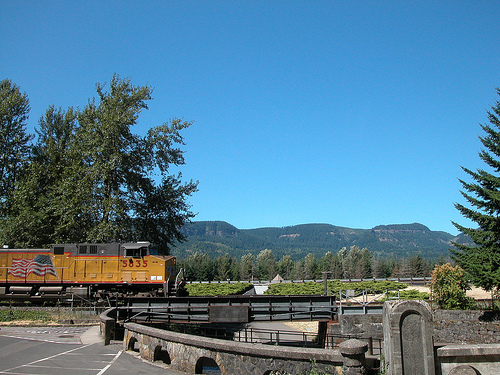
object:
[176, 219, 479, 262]
hill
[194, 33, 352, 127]
sky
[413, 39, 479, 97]
sky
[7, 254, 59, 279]
flag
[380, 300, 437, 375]
pillar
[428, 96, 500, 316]
tree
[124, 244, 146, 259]
window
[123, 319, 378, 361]
line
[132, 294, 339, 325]
bridge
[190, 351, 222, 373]
river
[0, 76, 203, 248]
tree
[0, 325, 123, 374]
parking lot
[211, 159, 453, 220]
sky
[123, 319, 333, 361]
edge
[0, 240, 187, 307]
train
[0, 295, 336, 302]
tracks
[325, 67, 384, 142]
part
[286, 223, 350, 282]
part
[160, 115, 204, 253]
part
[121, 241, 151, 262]
part